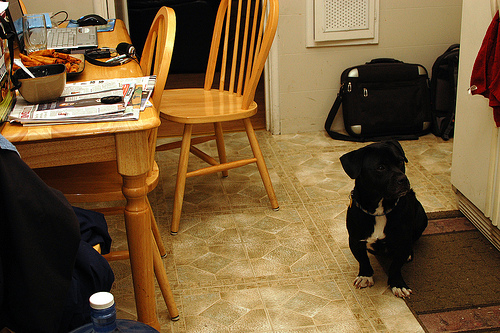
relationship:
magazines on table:
[17, 75, 155, 121] [0, 15, 180, 331]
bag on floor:
[325, 58, 434, 142] [159, 140, 459, 331]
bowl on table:
[17, 67, 65, 103] [0, 15, 180, 331]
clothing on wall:
[468, 11, 499, 132] [452, 2, 499, 250]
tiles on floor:
[158, 136, 341, 327] [159, 140, 459, 331]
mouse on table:
[78, 15, 106, 27] [0, 15, 180, 331]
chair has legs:
[162, 0, 284, 235] [159, 117, 279, 236]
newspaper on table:
[18, 86, 120, 116] [0, 15, 180, 331]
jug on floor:
[64, 289, 160, 331] [159, 140, 459, 331]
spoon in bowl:
[14, 58, 36, 81] [17, 67, 65, 103]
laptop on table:
[4, 1, 97, 48] [0, 15, 180, 331]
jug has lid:
[64, 289, 160, 331] [89, 289, 114, 308]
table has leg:
[0, 15, 180, 331] [118, 136, 153, 329]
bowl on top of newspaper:
[17, 67, 65, 103] [18, 86, 120, 116]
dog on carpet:
[331, 139, 434, 299] [383, 209, 499, 329]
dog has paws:
[331, 139, 434, 299] [354, 273, 412, 296]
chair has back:
[162, 0, 284, 235] [203, 0, 278, 110]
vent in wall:
[304, 0, 382, 47] [275, 3, 461, 132]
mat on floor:
[383, 209, 499, 329] [159, 140, 459, 331]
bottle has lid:
[64, 289, 160, 331] [89, 289, 114, 308]